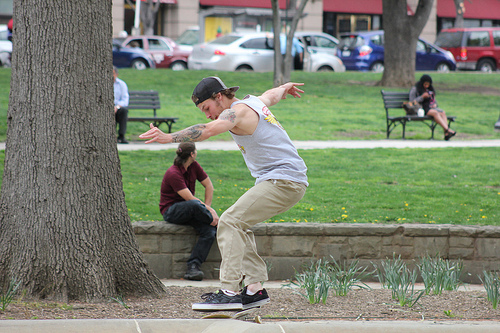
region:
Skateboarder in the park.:
[139, 71, 324, 309]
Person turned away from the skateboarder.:
[155, 138, 227, 285]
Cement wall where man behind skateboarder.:
[127, 215, 499, 286]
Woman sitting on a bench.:
[378, 73, 461, 139]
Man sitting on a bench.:
[113, 62, 178, 144]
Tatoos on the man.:
[171, 112, 241, 149]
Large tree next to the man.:
[8, 1, 166, 305]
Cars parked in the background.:
[4, 16, 497, 74]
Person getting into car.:
[269, 23, 316, 72]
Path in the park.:
[0, 130, 497, 156]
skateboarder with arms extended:
[126, 73, 311, 323]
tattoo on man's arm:
[163, 124, 211, 146]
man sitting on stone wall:
[155, 136, 226, 286]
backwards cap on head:
[184, 74, 243, 114]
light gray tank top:
[221, 95, 311, 192]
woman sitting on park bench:
[375, 68, 464, 141]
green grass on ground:
[320, 94, 361, 125]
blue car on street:
[344, 36, 378, 70]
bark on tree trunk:
[47, 79, 89, 177]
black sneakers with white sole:
[191, 285, 273, 313]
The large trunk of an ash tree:
[0, 0, 170, 301]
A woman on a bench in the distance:
[406, 74, 456, 141]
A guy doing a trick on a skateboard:
[136, 75, 308, 325]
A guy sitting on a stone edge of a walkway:
[158, 140, 221, 280]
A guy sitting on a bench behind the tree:
[101, 65, 177, 136]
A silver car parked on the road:
[184, 26, 346, 73]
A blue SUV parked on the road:
[339, 26, 456, 76]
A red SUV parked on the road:
[432, 23, 499, 73]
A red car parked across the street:
[112, 32, 199, 69]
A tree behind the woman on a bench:
[377, 0, 437, 85]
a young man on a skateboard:
[131, 67, 323, 321]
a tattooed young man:
[135, 69, 311, 307]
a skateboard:
[192, 304, 272, 324]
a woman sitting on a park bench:
[379, 73, 458, 142]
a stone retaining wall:
[128, 211, 497, 286]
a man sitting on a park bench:
[106, 64, 178, 141]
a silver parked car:
[182, 24, 350, 77]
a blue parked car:
[334, 25, 457, 76]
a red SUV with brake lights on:
[429, 21, 496, 71]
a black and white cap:
[188, 69, 238, 105]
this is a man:
[196, 77, 295, 292]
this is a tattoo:
[179, 126, 197, 138]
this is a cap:
[196, 73, 226, 90]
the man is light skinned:
[238, 106, 249, 121]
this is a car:
[198, 36, 269, 66]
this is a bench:
[383, 89, 409, 129]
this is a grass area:
[337, 143, 418, 213]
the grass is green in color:
[326, 164, 371, 201]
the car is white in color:
[230, 47, 240, 58]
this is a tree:
[19, 16, 107, 223]